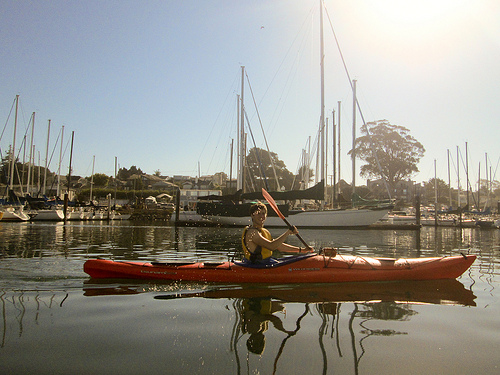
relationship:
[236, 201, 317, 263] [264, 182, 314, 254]
man has rowing stick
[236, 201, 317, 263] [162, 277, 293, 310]
man has shadow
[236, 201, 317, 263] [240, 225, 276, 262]
man has jacket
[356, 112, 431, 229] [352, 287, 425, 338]
tree has shadow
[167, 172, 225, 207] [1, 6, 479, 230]
building in background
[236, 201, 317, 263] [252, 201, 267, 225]
man has head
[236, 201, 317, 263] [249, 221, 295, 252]
man has arm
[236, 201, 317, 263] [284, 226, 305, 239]
man has hand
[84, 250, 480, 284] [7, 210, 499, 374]
boat on water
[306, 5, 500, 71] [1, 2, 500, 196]
sun in sky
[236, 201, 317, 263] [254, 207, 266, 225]
man has face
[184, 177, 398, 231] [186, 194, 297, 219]
boat has mask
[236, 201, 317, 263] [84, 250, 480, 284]
man in boat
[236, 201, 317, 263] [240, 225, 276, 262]
man wearing jacket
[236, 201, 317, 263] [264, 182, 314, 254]
man holding rowing stick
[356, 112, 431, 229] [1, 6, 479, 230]
tree in background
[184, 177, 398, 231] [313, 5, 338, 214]
boat has pole